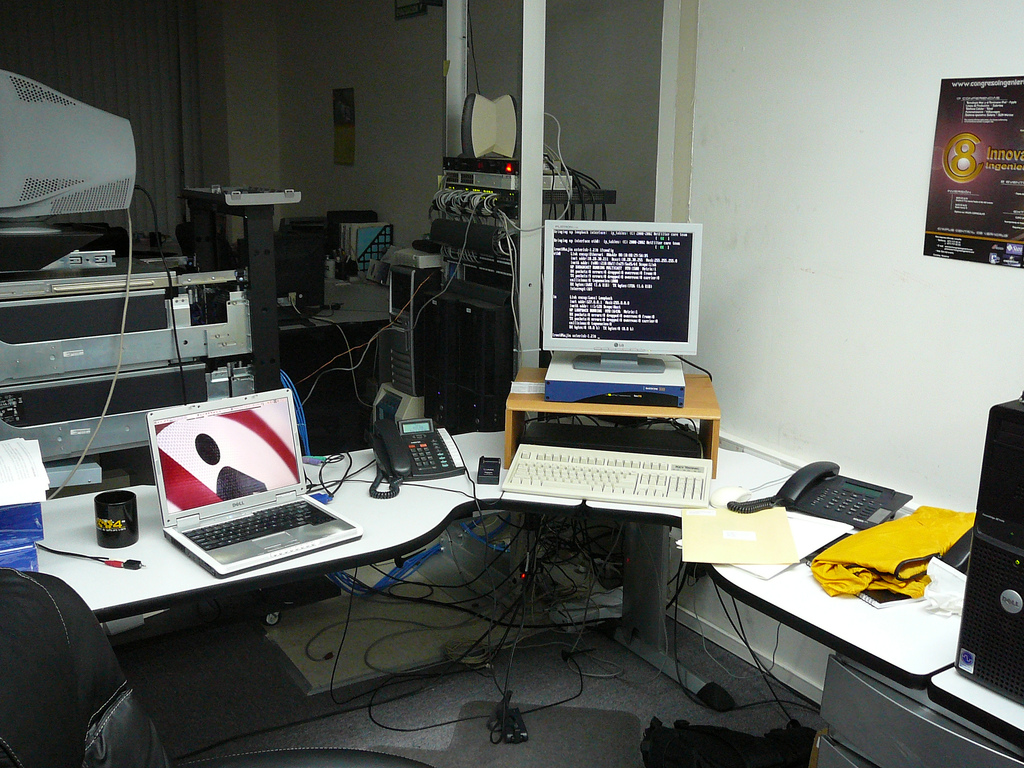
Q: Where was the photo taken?
A: It was taken at the office.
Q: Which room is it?
A: It is an office.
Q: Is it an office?
A: Yes, it is an office.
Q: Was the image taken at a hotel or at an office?
A: It was taken at an office.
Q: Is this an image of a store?
A: No, the picture is showing an office.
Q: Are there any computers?
A: Yes, there is a computer.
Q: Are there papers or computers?
A: Yes, there is a computer.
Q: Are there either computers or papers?
A: Yes, there is a computer.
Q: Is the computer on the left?
A: No, the computer is on the right of the image.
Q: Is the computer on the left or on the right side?
A: The computer is on the right of the image.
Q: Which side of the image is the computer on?
A: The computer is on the right of the image.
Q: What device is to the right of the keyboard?
A: The device is a computer.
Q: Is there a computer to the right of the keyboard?
A: Yes, there is a computer to the right of the keyboard.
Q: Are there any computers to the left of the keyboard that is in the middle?
A: No, the computer is to the right of the keyboard.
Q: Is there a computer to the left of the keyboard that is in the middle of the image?
A: No, the computer is to the right of the keyboard.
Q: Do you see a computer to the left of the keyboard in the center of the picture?
A: No, the computer is to the right of the keyboard.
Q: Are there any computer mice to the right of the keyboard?
A: No, there is a computer to the right of the keyboard.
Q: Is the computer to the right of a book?
A: No, the computer is to the right of a keyboard.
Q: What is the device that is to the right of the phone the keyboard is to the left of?
A: The device is a computer.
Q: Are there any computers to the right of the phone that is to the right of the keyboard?
A: Yes, there is a computer to the right of the telephone.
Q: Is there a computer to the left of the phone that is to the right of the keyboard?
A: No, the computer is to the right of the phone.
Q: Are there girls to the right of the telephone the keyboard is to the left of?
A: No, there is a computer to the right of the phone.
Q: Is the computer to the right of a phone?
A: Yes, the computer is to the right of a phone.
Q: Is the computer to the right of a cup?
A: No, the computer is to the right of a phone.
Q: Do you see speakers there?
A: Yes, there are speakers.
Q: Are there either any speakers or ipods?
A: Yes, there are speakers.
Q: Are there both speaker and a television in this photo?
A: No, there are speakers but no televisions.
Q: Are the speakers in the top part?
A: Yes, the speakers are in the top of the image.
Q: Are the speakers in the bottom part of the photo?
A: No, the speakers are in the top of the image.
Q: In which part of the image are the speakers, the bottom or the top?
A: The speakers are in the top of the image.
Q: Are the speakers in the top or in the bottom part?
A: The speakers are in the top of the image.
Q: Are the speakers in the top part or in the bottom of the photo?
A: The speakers are in the top of the image.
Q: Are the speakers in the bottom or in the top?
A: The speakers are in the top of the image.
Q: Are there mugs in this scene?
A: Yes, there is a mug.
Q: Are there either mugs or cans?
A: Yes, there is a mug.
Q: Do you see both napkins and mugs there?
A: No, there is a mug but no napkins.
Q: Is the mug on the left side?
A: Yes, the mug is on the left of the image.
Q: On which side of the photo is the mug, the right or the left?
A: The mug is on the left of the image.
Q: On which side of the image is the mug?
A: The mug is on the left of the image.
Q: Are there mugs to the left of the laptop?
A: Yes, there is a mug to the left of the laptop.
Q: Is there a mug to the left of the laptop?
A: Yes, there is a mug to the left of the laptop.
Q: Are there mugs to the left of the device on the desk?
A: Yes, there is a mug to the left of the laptop.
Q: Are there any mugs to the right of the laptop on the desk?
A: No, the mug is to the left of the laptop.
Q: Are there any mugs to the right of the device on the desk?
A: No, the mug is to the left of the laptop.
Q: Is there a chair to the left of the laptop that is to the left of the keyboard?
A: No, there is a mug to the left of the laptop.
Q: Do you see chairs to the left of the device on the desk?
A: No, there is a mug to the left of the laptop.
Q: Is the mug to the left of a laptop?
A: Yes, the mug is to the left of a laptop.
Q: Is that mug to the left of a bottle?
A: No, the mug is to the left of a laptop.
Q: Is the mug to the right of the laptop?
A: No, the mug is to the left of the laptop.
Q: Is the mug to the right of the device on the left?
A: No, the mug is to the left of the laptop.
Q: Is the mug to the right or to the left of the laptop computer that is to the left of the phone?
A: The mug is to the left of the laptop.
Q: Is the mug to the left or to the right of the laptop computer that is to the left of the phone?
A: The mug is to the left of the laptop.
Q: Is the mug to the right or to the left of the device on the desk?
A: The mug is to the left of the laptop.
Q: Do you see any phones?
A: Yes, there is a phone.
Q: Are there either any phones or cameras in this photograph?
A: Yes, there is a phone.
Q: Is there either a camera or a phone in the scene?
A: Yes, there is a phone.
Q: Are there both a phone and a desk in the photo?
A: Yes, there are both a phone and a desk.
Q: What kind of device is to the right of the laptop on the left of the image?
A: The device is a phone.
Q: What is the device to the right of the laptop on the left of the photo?
A: The device is a phone.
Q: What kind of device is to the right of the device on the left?
A: The device is a phone.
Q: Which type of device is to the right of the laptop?
A: The device is a phone.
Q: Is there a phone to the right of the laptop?
A: Yes, there is a phone to the right of the laptop.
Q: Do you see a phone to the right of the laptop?
A: Yes, there is a phone to the right of the laptop.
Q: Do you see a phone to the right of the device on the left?
A: Yes, there is a phone to the right of the laptop.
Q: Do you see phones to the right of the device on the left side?
A: Yes, there is a phone to the right of the laptop.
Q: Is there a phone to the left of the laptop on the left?
A: No, the phone is to the right of the laptop computer.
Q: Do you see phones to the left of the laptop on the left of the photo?
A: No, the phone is to the right of the laptop computer.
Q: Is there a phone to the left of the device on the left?
A: No, the phone is to the right of the laptop computer.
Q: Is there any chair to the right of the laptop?
A: No, there is a phone to the right of the laptop.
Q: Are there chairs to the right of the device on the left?
A: No, there is a phone to the right of the laptop.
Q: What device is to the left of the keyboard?
A: The device is a phone.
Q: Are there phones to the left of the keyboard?
A: Yes, there is a phone to the left of the keyboard.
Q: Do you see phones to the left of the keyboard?
A: Yes, there is a phone to the left of the keyboard.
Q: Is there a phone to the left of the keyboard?
A: Yes, there is a phone to the left of the keyboard.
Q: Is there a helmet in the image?
A: No, there are no helmets.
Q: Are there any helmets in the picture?
A: No, there are no helmets.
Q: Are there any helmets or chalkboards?
A: No, there are no helmets or chalkboards.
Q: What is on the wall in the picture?
A: The poster is on the wall.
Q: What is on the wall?
A: The poster is on the wall.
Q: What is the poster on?
A: The poster is on the wall.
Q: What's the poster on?
A: The poster is on the wall.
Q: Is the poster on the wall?
A: Yes, the poster is on the wall.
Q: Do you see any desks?
A: Yes, there is a desk.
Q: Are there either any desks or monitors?
A: Yes, there is a desk.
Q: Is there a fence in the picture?
A: No, there are no fences.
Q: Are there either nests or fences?
A: No, there are no fences or nests.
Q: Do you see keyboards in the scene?
A: Yes, there is a keyboard.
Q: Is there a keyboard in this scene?
A: Yes, there is a keyboard.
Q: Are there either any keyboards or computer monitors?
A: Yes, there is a keyboard.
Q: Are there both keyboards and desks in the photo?
A: Yes, there are both a keyboard and a desk.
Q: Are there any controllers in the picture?
A: No, there are no controllers.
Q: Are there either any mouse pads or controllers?
A: No, there are no controllers or mouse pads.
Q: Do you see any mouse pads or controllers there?
A: No, there are no controllers or mouse pads.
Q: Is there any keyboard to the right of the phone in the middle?
A: Yes, there is a keyboard to the right of the phone.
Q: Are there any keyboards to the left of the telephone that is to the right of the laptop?
A: No, the keyboard is to the right of the phone.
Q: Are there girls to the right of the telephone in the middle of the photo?
A: No, there is a keyboard to the right of the phone.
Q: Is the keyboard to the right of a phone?
A: Yes, the keyboard is to the right of a phone.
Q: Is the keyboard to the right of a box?
A: No, the keyboard is to the right of a phone.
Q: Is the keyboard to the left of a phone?
A: No, the keyboard is to the right of a phone.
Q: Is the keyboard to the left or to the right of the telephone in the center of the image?
A: The keyboard is to the right of the phone.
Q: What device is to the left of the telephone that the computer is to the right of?
A: The device is a keyboard.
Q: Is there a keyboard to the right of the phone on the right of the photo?
A: No, the keyboard is to the left of the phone.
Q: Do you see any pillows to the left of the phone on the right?
A: No, there is a keyboard to the left of the phone.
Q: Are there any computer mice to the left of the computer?
A: No, there is a keyboard to the left of the computer.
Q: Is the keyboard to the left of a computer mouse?
A: No, the keyboard is to the left of the computer.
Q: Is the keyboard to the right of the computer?
A: No, the keyboard is to the left of the computer.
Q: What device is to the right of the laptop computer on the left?
A: The device is a keyboard.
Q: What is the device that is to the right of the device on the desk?
A: The device is a keyboard.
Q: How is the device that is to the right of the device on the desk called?
A: The device is a keyboard.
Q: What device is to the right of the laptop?
A: The device is a keyboard.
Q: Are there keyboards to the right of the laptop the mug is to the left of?
A: Yes, there is a keyboard to the right of the laptop.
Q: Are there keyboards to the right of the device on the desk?
A: Yes, there is a keyboard to the right of the laptop.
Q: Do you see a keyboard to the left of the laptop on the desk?
A: No, the keyboard is to the right of the laptop.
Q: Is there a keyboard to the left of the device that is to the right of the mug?
A: No, the keyboard is to the right of the laptop.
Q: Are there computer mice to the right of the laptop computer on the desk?
A: No, there is a keyboard to the right of the laptop.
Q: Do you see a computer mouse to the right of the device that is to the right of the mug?
A: No, there is a keyboard to the right of the laptop.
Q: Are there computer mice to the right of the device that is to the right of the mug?
A: No, there is a keyboard to the right of the laptop.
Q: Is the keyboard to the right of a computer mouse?
A: No, the keyboard is to the right of the laptop.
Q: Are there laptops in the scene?
A: Yes, there is a laptop.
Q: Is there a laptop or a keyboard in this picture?
A: Yes, there is a laptop.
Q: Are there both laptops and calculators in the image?
A: No, there is a laptop but no calculators.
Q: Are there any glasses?
A: No, there are no glasses.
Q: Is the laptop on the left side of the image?
A: Yes, the laptop is on the left of the image.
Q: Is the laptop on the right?
A: No, the laptop is on the left of the image.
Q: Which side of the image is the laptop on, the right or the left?
A: The laptop is on the left of the image.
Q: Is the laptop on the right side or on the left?
A: The laptop is on the left of the image.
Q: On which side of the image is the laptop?
A: The laptop is on the left of the image.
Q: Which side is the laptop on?
A: The laptop is on the left of the image.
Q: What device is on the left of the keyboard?
A: The device is a laptop.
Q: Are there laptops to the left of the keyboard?
A: Yes, there is a laptop to the left of the keyboard.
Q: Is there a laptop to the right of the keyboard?
A: No, the laptop is to the left of the keyboard.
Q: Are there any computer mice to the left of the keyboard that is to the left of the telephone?
A: No, there is a laptop to the left of the keyboard.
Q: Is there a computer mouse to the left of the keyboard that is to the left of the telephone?
A: No, there is a laptop to the left of the keyboard.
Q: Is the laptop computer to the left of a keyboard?
A: Yes, the laptop computer is to the left of a keyboard.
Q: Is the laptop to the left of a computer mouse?
A: No, the laptop is to the left of a keyboard.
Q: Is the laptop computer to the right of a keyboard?
A: No, the laptop computer is to the left of a keyboard.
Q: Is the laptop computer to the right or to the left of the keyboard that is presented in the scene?
A: The laptop computer is to the left of the keyboard.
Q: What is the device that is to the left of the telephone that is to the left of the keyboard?
A: The device is a laptop.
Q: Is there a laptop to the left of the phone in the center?
A: Yes, there is a laptop to the left of the telephone.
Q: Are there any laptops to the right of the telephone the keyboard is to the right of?
A: No, the laptop is to the left of the phone.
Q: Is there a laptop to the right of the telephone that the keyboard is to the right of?
A: No, the laptop is to the left of the phone.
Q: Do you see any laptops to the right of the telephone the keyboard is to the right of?
A: No, the laptop is to the left of the phone.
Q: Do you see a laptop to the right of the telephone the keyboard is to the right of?
A: No, the laptop is to the left of the phone.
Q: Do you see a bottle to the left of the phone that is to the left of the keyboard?
A: No, there is a laptop to the left of the phone.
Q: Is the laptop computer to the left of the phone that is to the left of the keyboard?
A: Yes, the laptop computer is to the left of the phone.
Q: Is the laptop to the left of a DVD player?
A: No, the laptop is to the left of the phone.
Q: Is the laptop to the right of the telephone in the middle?
A: No, the laptop is to the left of the telephone.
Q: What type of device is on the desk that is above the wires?
A: The device is a laptop.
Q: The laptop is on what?
A: The laptop is on the desk.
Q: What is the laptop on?
A: The laptop is on the desk.